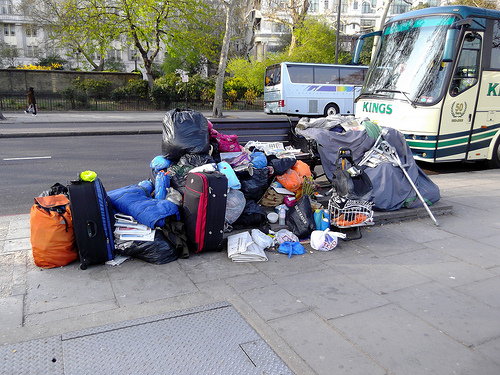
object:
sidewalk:
[0, 167, 499, 373]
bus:
[265, 62, 369, 119]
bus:
[351, 5, 499, 169]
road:
[0, 126, 357, 217]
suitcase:
[183, 169, 230, 257]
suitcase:
[68, 170, 118, 271]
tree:
[1, 0, 225, 88]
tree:
[226, 0, 347, 98]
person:
[25, 85, 38, 114]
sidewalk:
[2, 108, 299, 136]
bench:
[207, 118, 314, 177]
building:
[0, 1, 210, 83]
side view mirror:
[441, 27, 459, 61]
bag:
[29, 193, 79, 267]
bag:
[309, 227, 346, 252]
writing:
[362, 102, 393, 115]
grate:
[0, 303, 297, 374]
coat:
[107, 182, 182, 230]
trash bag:
[161, 108, 211, 162]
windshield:
[360, 15, 460, 105]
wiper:
[376, 89, 419, 110]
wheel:
[324, 103, 340, 117]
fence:
[0, 93, 265, 112]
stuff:
[29, 172, 184, 270]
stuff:
[219, 150, 320, 262]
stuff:
[293, 118, 442, 223]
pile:
[29, 110, 442, 266]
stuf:
[27, 170, 125, 270]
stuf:
[153, 113, 283, 256]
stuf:
[106, 173, 186, 267]